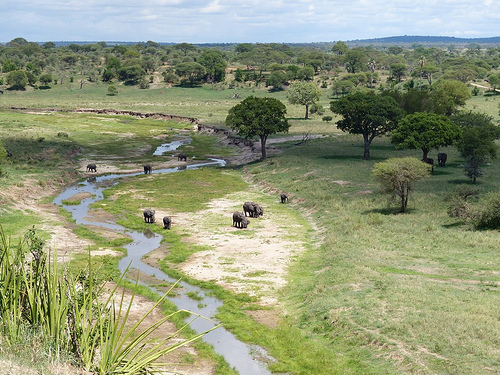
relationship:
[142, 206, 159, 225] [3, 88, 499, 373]
elephant in field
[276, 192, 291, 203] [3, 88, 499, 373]
elephant in field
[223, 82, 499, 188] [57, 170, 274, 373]
trees near stream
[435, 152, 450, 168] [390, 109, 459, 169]
elephant under tree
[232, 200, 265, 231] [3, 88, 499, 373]
elephants in field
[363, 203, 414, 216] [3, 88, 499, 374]
shadow on ground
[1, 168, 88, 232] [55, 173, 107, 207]
ridge near water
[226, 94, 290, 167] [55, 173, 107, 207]
trees near water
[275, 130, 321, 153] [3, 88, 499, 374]
branch on ground